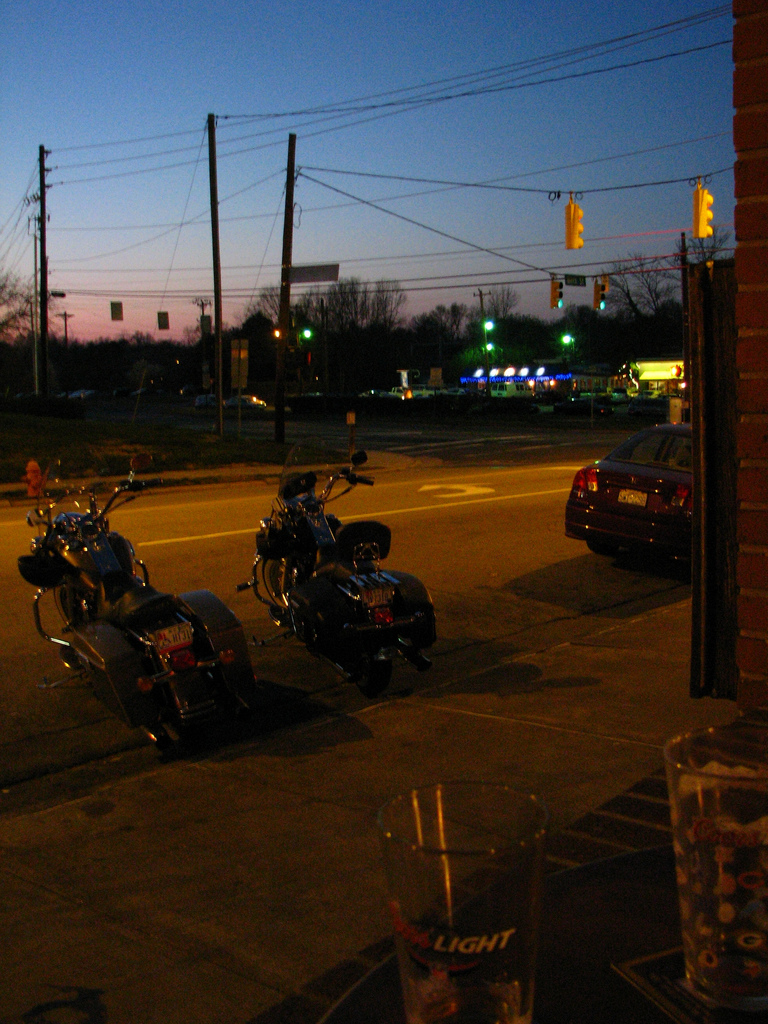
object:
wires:
[0, 5, 735, 296]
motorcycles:
[17, 435, 438, 763]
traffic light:
[694, 178, 715, 236]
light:
[484, 321, 492, 329]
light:
[562, 336, 570, 344]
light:
[302, 328, 314, 341]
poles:
[24, 143, 261, 434]